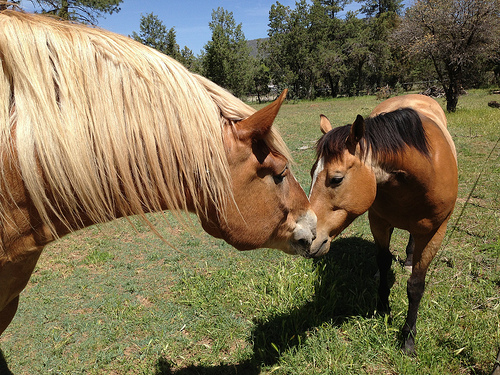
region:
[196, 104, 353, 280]
Two horses are kissing.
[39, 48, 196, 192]
The horse has blonde hair.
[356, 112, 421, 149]
The horse has black hair.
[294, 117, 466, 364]
A horse standing in the grass.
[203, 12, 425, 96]
Trees in the background.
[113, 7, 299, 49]
The sky is clear and blue.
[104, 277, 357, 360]
The grass is green.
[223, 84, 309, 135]
The horse has ear.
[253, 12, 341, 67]
The tree has leaves.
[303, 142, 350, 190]
The horse has an eye.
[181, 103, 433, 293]
two horses are touching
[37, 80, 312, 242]
the horse has blonde hair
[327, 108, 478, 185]
the horse has dark hair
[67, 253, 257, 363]
the grass is dead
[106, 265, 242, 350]
the grass is on the ground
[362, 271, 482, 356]
the horse has doark hooves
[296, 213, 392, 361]
the horse's shadow is on the ground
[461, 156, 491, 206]
a fence's shadow is on the ground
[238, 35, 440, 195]
trees are in the distance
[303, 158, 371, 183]
the horse has a dark eye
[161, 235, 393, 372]
the shadow of the horse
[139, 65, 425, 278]
taking care each other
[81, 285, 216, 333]
some grass in the field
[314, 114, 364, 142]
the two ears of the horse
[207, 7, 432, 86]
several trees in the distance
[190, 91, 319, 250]
the head of the horse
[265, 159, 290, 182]
one eye of the brown horse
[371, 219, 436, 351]
the two front legs of the horse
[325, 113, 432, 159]
the black horse's mane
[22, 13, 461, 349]
two horses on the scene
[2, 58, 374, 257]
horses on the rgass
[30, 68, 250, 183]
mane of the horse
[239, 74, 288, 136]
ear of the horse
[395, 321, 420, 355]
hoof of the horse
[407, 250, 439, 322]
leg of the horse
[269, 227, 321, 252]
snout of the horse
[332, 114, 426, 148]
mane of the horse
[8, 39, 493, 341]
horses are close together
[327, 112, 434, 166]
horse has dark brown mane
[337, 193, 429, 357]
horse has brown legs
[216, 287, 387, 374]
green grass under horses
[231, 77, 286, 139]
horse has brown ears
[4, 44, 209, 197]
horse has light brown mane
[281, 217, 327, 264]
horse has brown nose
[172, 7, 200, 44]
no clouds in sky